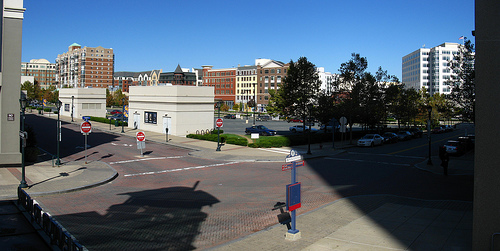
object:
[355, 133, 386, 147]
cars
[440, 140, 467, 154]
cars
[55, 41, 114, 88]
building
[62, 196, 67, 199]
brick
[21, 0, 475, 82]
sky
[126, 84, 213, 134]
building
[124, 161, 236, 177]
lines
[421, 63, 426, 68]
windows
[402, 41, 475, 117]
offfice building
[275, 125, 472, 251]
shadow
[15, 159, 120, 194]
corner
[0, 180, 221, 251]
intersection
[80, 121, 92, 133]
circle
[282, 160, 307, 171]
sign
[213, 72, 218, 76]
windows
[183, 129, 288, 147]
grass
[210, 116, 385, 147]
parking lot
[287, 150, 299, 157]
sign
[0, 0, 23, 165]
building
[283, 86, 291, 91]
leaves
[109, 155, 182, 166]
lines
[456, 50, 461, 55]
windows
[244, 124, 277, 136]
cars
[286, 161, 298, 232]
pole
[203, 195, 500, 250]
sidewalk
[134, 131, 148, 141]
sign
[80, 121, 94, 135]
sign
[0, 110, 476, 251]
road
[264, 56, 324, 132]
tree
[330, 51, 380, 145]
tree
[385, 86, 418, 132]
tree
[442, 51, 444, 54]
window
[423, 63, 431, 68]
window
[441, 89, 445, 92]
window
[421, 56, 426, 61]
window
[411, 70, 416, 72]
window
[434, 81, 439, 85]
window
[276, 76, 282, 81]
window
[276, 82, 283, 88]
window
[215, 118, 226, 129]
sign